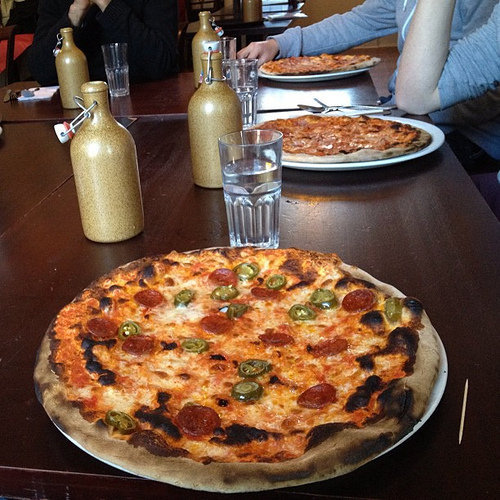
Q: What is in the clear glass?
A: Water.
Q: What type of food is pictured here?
A: Pizza.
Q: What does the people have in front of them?
A: Pizza.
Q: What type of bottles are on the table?
A: Gold glass bottles.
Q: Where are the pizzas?
A: On the table.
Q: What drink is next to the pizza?
A: Water.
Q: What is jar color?
A: Olive green.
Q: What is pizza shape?
A: Round.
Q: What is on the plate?
A: Pasta.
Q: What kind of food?
A: Pizza.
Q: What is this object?
A: Glass.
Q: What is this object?
A: Bottle.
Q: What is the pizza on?
A: Dish.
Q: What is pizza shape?
A: Round.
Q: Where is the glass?
A: On the table.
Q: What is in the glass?
A: Water.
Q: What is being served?
A: Pizza.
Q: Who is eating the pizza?
A: The people at the table.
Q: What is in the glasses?
A: Water.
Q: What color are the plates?
A: White.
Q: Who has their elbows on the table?
A: Both people.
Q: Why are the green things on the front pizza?
A: Jalepeno peppers.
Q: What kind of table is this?
A: A wood table.